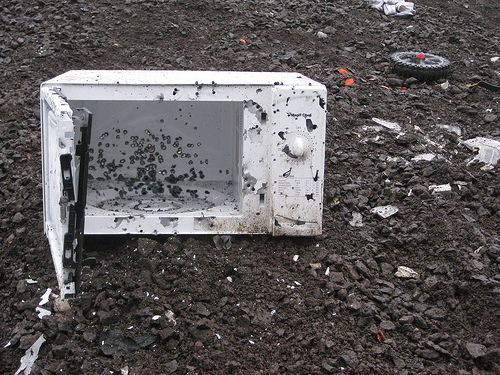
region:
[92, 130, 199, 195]
particles in the microwave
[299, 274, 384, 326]
rocks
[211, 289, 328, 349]
small rocks on the ground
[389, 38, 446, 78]
a wheel on the ground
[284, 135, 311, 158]
a knob on the microwave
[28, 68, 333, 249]
a microwave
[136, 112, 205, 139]
inside of the micorwave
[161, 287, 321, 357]
the rocks are black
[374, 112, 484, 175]
white particles on the ground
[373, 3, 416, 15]
an object on the ground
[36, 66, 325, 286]
a busted up microwave sitting on the ground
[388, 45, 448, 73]
the wheel of a toy sitting on the dirt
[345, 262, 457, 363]
a bunch of rocks on the ground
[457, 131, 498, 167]
a piece of plastic sitting on the ground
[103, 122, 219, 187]
a bunch of dirty marks inside the microwave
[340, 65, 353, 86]
something red sitting on the ground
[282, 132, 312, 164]
the button on the microwave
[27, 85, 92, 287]
the broken door of the microwave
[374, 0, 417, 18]
some dirty white clothes on the ground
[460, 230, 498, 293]
some more rocks on the ground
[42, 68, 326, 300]
old white microwave full of bullet holes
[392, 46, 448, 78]
black wheel from a lawnmower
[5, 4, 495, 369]
black dirt and gravel ground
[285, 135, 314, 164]
dial on the front of the microwave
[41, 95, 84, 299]
the microwave door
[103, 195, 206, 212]
area for glass plate in microwave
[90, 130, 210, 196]
back wall of microwave full of bullet holes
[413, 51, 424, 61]
red center of the tire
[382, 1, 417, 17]
stray piece white cloth on the ground above the wheel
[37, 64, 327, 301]
a beat-up microwave at a dump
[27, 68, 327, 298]
a white microwave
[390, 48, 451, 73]
a wheel on the ground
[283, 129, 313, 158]
the dial of the microwave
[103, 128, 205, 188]
bullet holes in the microwave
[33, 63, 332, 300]
a beat up microwave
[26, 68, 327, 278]
a microwave with bullet holes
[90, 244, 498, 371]
dirt in front of the microwave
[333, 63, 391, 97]
orange pieces on the ground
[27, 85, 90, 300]
the door of the microwave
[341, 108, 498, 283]
broken pieces of the microwave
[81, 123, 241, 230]
many holes in back of microwave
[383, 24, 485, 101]
a wheel on the ground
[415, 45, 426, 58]
a red spot on wheel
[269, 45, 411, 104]
orange particles on the ground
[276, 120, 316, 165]
one knob on the front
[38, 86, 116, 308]
black part breaking off door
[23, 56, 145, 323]
open door of microwave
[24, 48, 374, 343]
an old white microwave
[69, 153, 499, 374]
brown rocks on the ground